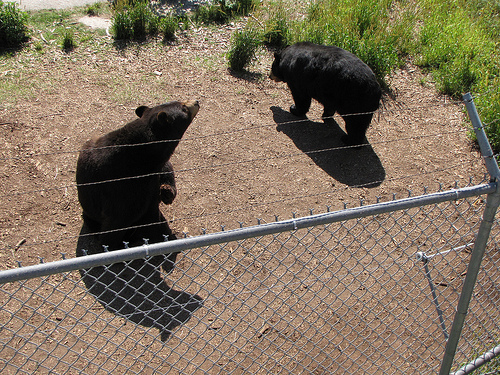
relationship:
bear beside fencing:
[263, 41, 381, 152] [2, 94, 500, 373]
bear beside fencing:
[72, 96, 205, 256] [2, 94, 500, 373]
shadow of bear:
[262, 99, 392, 194] [263, 41, 381, 152]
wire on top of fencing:
[3, 88, 496, 272] [2, 94, 500, 373]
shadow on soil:
[262, 99, 392, 194] [1, 53, 499, 374]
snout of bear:
[193, 99, 201, 109] [72, 96, 205, 256]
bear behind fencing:
[263, 41, 381, 152] [2, 94, 500, 373]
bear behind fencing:
[72, 96, 205, 256] [2, 94, 500, 373]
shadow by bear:
[262, 99, 392, 194] [263, 41, 381, 152]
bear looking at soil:
[263, 41, 381, 149] [1, 53, 499, 374]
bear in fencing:
[263, 41, 381, 152] [2, 94, 500, 373]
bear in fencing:
[72, 96, 205, 256] [2, 94, 500, 373]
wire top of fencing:
[3, 88, 496, 272] [2, 94, 500, 373]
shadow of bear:
[73, 209, 207, 341] [72, 96, 205, 256]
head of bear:
[131, 95, 201, 152] [72, 96, 205, 256]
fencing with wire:
[2, 94, 500, 373] [3, 88, 496, 272]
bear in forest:
[263, 41, 381, 149] [17, 22, 494, 364]